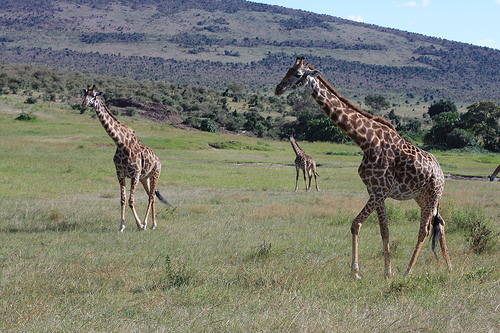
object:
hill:
[0, 0, 499, 154]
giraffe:
[286, 136, 320, 193]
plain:
[0, 63, 499, 331]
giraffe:
[274, 57, 452, 281]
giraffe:
[80, 85, 175, 233]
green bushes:
[201, 118, 218, 133]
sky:
[242, 0, 499, 52]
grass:
[165, 255, 176, 283]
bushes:
[14, 112, 35, 121]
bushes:
[201, 119, 218, 133]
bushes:
[99, 82, 112, 88]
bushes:
[126, 108, 138, 116]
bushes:
[161, 98, 176, 107]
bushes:
[240, 119, 257, 132]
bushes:
[197, 120, 216, 131]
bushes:
[163, 44, 168, 49]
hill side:
[0, 0, 499, 150]